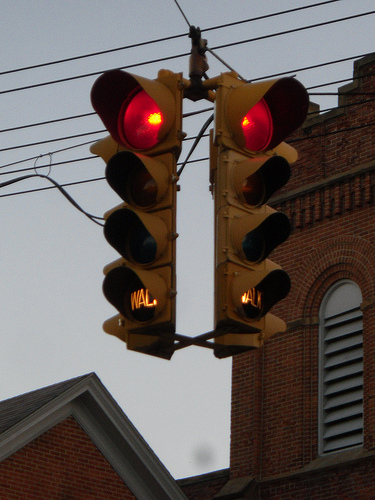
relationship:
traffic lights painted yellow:
[70, 52, 322, 374] [115, 274, 163, 329]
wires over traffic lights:
[2, 2, 374, 68] [70, 52, 322, 374]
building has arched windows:
[207, 45, 374, 500] [305, 265, 374, 470]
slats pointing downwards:
[305, 265, 374, 470] [317, 301, 365, 453]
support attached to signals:
[125, 15, 270, 71] [70, 52, 322, 374]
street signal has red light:
[70, 52, 322, 374] [110, 82, 171, 154]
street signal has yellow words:
[70, 52, 322, 374] [123, 282, 160, 315]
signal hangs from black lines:
[70, 52, 322, 374] [2, 2, 374, 68]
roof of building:
[8, 364, 89, 429] [6, 366, 180, 500]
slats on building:
[8, 364, 89, 429] [6, 366, 180, 500]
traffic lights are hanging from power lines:
[70, 52, 322, 374] [2, 2, 374, 68]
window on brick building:
[305, 265, 374, 470] [207, 45, 374, 500]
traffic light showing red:
[70, 52, 322, 374] [116, 92, 280, 164]